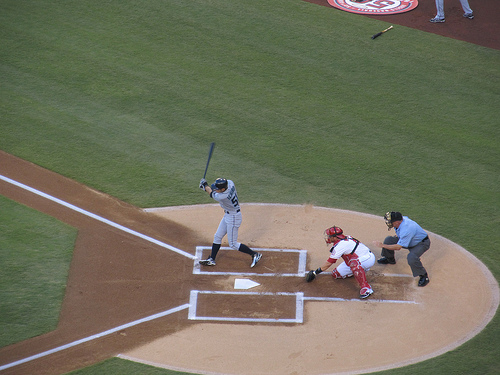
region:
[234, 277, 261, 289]
the home plate on the baseball field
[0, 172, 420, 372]
the white lines on the baseball field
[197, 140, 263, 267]
the baseball player up to bat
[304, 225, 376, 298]
the catcher crouching down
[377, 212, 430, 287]
the umpire behind the catcher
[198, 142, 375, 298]
the baseball players on the field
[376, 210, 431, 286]
the umpire on the field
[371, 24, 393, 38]
the bat on the ground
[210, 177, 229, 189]
the helmet on the batter's head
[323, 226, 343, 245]
the helmet and mask on the catcher's head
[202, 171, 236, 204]
Ichiro has black helmet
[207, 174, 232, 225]
green and grey shirt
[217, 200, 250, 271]
player has grey pants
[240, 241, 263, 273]
black and white shoes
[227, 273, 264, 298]
home plate is white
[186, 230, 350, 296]
white lines in batter's box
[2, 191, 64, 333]
green grass on infield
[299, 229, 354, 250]
catcher has red helmet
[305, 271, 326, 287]
catcher has dark glove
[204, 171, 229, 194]
head of a person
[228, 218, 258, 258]
leg of a person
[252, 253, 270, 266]
feet of a person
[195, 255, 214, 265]
feet of a person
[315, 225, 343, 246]
head of a person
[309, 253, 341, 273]
arm of a person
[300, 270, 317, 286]
hand of a person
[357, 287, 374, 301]
feet of a person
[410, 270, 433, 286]
feet of a person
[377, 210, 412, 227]
head of a person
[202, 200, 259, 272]
leg of a person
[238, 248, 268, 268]
feet of a person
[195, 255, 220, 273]
feet of a person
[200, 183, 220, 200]
arm of a person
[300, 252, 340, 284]
arm of a person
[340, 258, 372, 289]
leg of a person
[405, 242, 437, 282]
leg of a person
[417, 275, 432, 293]
feet of a person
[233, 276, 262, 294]
White home base plate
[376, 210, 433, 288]
Man wearing black shoes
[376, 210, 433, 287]
Man wearing grey pants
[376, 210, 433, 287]
Man wearing blue shirt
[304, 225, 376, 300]
Man wearing red hat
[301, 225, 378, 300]
Man wearing face gaurd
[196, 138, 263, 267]
Baseball player holding black bat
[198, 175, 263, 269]
Baseball player wearing black socks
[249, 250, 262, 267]
Black and white shoe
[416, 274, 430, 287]
Blue shoe